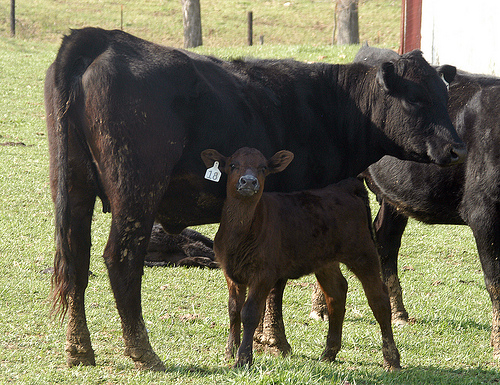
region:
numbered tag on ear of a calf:
[190, 135, 289, 206]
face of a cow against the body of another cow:
[362, 20, 482, 240]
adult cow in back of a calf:
[210, 41, 475, 336]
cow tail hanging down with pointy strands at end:
[35, 50, 95, 340]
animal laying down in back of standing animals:
[47, 147, 234, 327]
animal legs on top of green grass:
[41, 306, 471, 374]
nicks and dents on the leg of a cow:
[92, 90, 157, 302]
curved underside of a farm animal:
[370, 175, 486, 230]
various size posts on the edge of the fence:
[1, 5, 371, 31]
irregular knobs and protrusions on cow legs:
[53, 318, 313, 373]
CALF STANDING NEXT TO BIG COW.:
[31, 22, 474, 368]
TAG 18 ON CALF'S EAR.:
[200, 149, 228, 186]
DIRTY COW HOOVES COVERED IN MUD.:
[55, 296, 175, 374]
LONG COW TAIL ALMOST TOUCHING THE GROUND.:
[48, 29, 78, 314]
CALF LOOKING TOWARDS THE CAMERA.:
[192, 143, 306, 208]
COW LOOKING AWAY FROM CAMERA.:
[294, 42, 486, 184]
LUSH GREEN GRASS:
[425, 270, 477, 375]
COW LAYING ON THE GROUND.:
[146, 228, 216, 273]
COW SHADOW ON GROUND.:
[331, 356, 491, 384]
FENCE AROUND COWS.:
[165, 6, 392, 46]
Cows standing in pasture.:
[38, 21, 493, 371]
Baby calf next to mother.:
[200, 146, 412, 373]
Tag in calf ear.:
[199, 156, 226, 183]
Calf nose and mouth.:
[238, 174, 260, 192]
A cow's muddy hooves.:
[62, 311, 162, 369]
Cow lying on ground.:
[141, 225, 217, 269]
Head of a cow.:
[376, 48, 471, 170]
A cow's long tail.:
[44, 24, 86, 325]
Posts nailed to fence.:
[181, 3, 376, 48]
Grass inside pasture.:
[266, 359, 381, 379]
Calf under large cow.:
[53, 50, 444, 375]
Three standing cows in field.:
[35, 45, 495, 365]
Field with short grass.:
[2, 6, 472, 381]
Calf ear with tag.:
[197, 145, 229, 200]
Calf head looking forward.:
[200, 141, 300, 216]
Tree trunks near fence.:
[157, 1, 382, 51]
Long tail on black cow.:
[42, 62, 133, 364]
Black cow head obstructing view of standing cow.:
[354, 40, 499, 337]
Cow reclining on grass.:
[146, 217, 241, 300]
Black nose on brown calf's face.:
[226, 150, 262, 224]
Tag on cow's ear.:
[206, 160, 226, 188]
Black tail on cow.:
[45, 77, 102, 307]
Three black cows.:
[19, 12, 496, 362]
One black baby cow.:
[193, 137, 408, 383]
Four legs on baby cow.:
[212, 262, 415, 380]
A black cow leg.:
[98, 194, 172, 381]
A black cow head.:
[357, 44, 476, 192]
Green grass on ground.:
[405, 261, 476, 371]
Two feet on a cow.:
[53, 332, 176, 378]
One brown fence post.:
[227, 3, 279, 54]